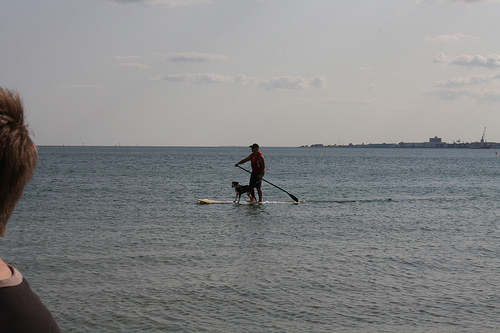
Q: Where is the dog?
A: On the surfboard.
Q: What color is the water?
A: Blue.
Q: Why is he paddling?
A: To move.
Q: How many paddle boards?
A: 1.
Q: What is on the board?
A: Dog.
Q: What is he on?
A: The water.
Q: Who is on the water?
A: The man.